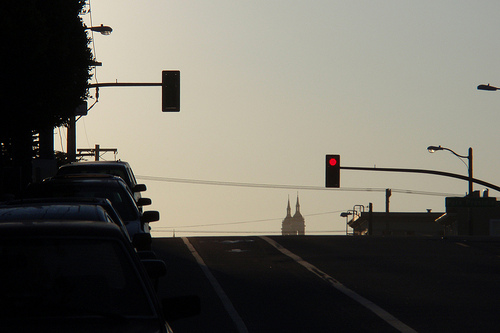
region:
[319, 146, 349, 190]
traffic light on a pole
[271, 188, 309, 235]
top of church on the hill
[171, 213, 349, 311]
white lines in the street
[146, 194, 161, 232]
mirror on the car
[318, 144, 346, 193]
red light for the traffic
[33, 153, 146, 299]
cars on the side of road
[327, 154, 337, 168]
the light is red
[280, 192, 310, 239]
the steeple in distance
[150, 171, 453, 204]
wires across the street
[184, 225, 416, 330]
lines on the road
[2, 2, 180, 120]
tree behind the light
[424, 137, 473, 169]
light on the pole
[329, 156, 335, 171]
red light on the signal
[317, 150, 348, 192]
A traffic light in the STOP position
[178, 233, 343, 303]
A road sloping upward with white markings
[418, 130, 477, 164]
The top of a streetlight extending over the street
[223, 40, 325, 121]
An empty gray portion of sky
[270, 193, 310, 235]
Two building towers seen in the distance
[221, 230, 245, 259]
White arrows marked on the street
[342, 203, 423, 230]
A section of a flat building roof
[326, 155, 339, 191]
traffic light on red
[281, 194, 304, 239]
double spires rise over a hill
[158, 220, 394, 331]
lines painted in the road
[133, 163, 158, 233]
side view mirrors of parked cars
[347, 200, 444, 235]
rooftop of a building on the other side of the hill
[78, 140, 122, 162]
top of a utility pole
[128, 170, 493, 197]
utility lines cross over the road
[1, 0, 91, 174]
tree to the side of the road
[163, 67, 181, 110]
back of a traffic light for oncoming traffic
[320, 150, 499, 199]
traffic signal on long pole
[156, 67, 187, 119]
back of rectangular traffic signal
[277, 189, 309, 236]
two hazy distant spires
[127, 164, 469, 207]
wires running across street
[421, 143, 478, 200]
street lamp on tall pole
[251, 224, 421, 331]
traffic divider line on street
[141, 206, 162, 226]
rear view mirror on parked car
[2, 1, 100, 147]
outline of tree near street side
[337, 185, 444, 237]
top portion of distant building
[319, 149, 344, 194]
traffic signal with red light lit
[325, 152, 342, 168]
red light on traffic signal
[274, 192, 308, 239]
two spires in the distance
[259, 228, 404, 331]
lane divider line in middle of street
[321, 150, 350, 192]
a round red light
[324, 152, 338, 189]
light is attached to pole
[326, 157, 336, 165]
light is red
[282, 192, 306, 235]
tall building is behind the hill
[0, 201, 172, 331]
car is parked beside the road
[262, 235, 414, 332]
white line is in the street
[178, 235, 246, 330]
line is white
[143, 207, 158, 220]
rear view mirror is apart of car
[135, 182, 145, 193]
rear view mirror is apart of car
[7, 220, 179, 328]
A car on a street.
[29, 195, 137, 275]
A car on a street.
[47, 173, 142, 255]
A car on a street.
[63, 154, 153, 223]
A car on a street.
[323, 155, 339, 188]
A regular street light.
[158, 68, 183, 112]
A regular street light.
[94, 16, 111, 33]
A regular street light.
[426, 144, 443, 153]
A regular street light.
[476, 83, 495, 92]
A regular street light.